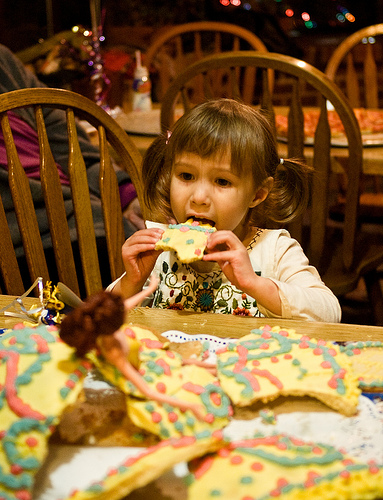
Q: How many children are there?
A: One.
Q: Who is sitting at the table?
A: A woman.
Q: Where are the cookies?
A: On the table.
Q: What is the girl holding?
A: A cookie.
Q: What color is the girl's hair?
A: Brown.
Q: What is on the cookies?
A: Frosting.